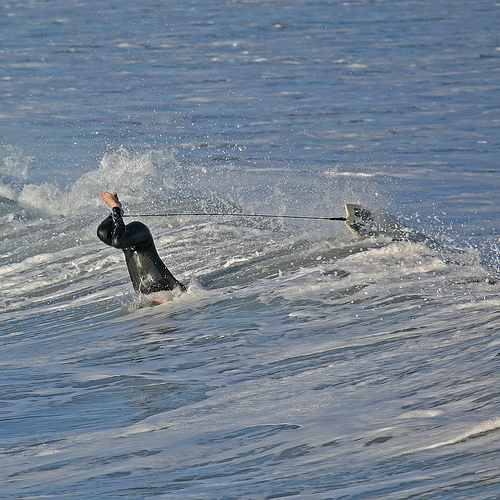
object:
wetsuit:
[95, 206, 186, 295]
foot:
[100, 191, 120, 209]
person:
[95, 191, 187, 295]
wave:
[2, 194, 500, 401]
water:
[2, 1, 500, 500]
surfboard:
[344, 203, 437, 242]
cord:
[123, 213, 346, 221]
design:
[350, 207, 375, 236]